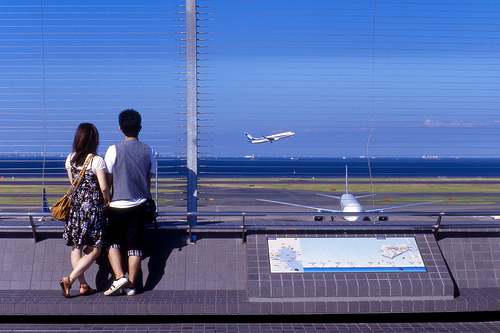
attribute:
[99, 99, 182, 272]
man — watching, brown, here, tan, short, looking, standing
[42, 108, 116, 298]
woman — watching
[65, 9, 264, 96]
sky — cloudless, spotless, blue, clear, above, massive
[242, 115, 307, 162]
plane — white, visable, taking off, flying, large